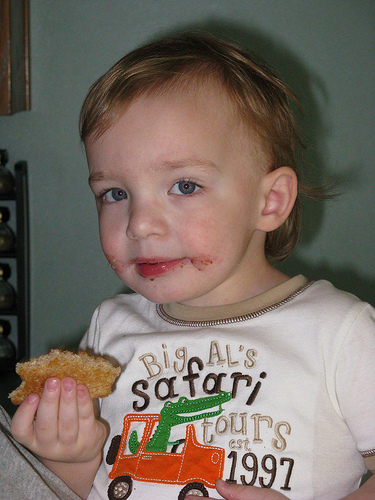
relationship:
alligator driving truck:
[128, 390, 232, 454] [110, 384, 236, 498]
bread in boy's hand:
[8, 348, 122, 407] [13, 372, 116, 476]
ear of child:
[247, 162, 303, 239] [7, 29, 375, 500]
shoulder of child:
[77, 293, 158, 356] [69, 28, 317, 489]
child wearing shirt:
[7, 29, 375, 500] [74, 274, 374, 498]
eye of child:
[163, 173, 209, 204] [7, 29, 375, 500]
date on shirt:
[226, 448, 297, 490] [29, 270, 374, 498]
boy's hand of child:
[9, 377, 106, 464] [7, 29, 375, 500]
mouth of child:
[105, 229, 197, 275] [52, 27, 371, 496]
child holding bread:
[7, 29, 375, 500] [8, 348, 122, 407]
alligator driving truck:
[128, 390, 232, 454] [100, 412, 228, 497]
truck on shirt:
[100, 412, 228, 497] [74, 274, 374, 498]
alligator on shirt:
[128, 390, 232, 454] [74, 274, 374, 498]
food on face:
[190, 256, 215, 272] [60, 48, 259, 320]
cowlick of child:
[185, 32, 305, 115] [7, 29, 375, 500]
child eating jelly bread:
[26, 20, 352, 360] [0, 326, 127, 434]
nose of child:
[123, 214, 176, 243] [79, 38, 323, 433]